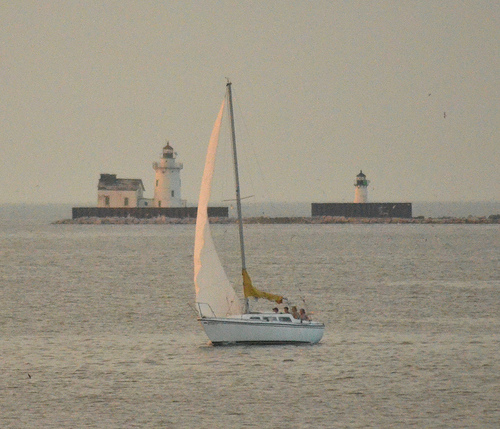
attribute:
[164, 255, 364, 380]
boat — white, sail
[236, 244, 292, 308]
flag — yellow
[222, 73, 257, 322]
pole — tall, metal, boat, silver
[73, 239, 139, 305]
water — calm, ripple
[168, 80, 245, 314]
sail — white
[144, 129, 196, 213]
light — white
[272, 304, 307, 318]
people — four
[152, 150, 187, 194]
house — light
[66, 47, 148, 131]
sky — calm